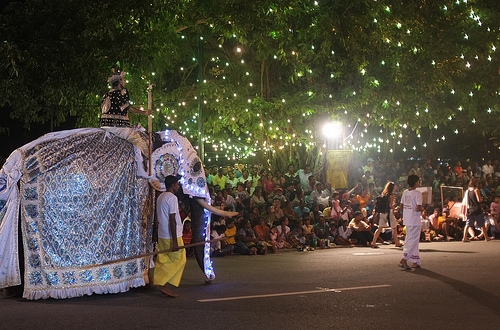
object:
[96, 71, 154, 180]
handler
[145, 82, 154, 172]
rod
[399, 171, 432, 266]
woman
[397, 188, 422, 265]
dress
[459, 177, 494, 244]
people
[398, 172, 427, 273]
woman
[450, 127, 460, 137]
lights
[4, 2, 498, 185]
trees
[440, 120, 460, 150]
grounds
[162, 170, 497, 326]
people road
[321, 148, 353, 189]
sign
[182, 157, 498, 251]
spectators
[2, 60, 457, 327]
parade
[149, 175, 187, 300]
man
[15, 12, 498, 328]
night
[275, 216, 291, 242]
person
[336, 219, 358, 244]
person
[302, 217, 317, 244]
person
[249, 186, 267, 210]
person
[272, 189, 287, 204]
person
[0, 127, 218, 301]
costume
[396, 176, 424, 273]
woman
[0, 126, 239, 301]
elephant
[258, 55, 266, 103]
branches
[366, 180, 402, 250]
people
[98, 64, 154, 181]
person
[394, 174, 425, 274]
people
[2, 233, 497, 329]
road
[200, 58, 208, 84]
branch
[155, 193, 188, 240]
shirt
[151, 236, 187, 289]
bottoms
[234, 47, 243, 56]
lights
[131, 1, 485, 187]
tree